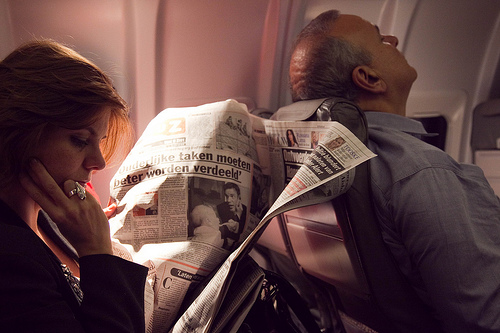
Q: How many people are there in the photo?
A: Two.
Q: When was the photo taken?
A: Night time.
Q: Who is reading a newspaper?
A: A woman.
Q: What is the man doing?
A: Sleeping.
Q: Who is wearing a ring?
A: The woman.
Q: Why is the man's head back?
A: Resting.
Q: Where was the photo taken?
A: Airplane.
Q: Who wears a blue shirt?
A: A man.